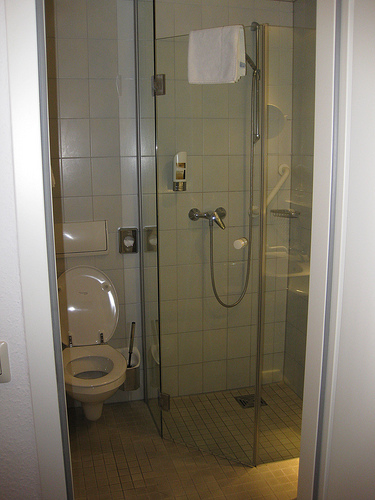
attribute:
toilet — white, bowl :
[50, 262, 142, 427]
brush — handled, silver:
[119, 317, 143, 366]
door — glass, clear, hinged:
[141, 19, 291, 468]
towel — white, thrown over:
[184, 26, 248, 84]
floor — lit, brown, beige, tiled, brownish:
[76, 406, 299, 494]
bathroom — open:
[3, 2, 349, 497]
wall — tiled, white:
[43, 2, 307, 404]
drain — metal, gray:
[226, 387, 269, 412]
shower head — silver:
[243, 56, 277, 151]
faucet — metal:
[178, 203, 230, 232]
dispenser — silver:
[116, 223, 143, 257]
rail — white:
[249, 153, 299, 226]